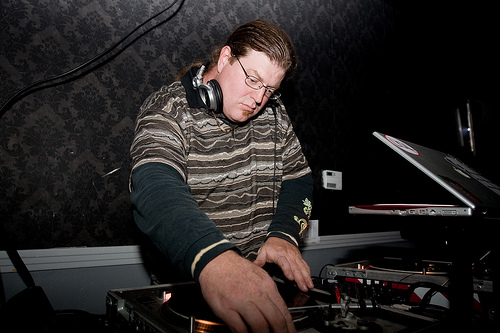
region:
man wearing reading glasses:
[231, 40, 288, 104]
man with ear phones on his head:
[173, 48, 239, 123]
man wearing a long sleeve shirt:
[130, 157, 240, 274]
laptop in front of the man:
[355, 118, 487, 243]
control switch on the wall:
[317, 156, 349, 193]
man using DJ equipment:
[186, 212, 308, 331]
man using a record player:
[108, 270, 345, 330]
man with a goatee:
[240, 108, 257, 120]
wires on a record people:
[317, 251, 373, 302]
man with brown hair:
[250, 28, 277, 53]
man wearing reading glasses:
[238, 69, 285, 99]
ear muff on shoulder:
[188, 75, 223, 118]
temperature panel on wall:
[312, 163, 351, 199]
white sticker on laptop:
[382, 130, 421, 162]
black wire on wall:
[51, 49, 97, 86]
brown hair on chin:
[237, 110, 255, 119]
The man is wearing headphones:
[193, 62, 221, 111]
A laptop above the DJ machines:
[348, 131, 496, 214]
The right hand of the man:
[201, 251, 295, 331]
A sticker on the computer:
[385, 135, 417, 155]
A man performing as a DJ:
[133, 20, 313, 331]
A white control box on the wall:
[323, 169, 343, 188]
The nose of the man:
[250, 83, 265, 103]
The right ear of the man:
[216, 45, 228, 72]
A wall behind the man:
[0, 2, 497, 252]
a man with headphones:
[140, 14, 306, 129]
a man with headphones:
[163, 18, 298, 130]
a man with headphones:
[137, 16, 317, 160]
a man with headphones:
[155, 23, 324, 155]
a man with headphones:
[155, 27, 347, 178]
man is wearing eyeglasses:
[211, 38, 298, 127]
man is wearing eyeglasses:
[215, 29, 272, 131]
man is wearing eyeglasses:
[217, 33, 298, 142]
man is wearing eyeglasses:
[185, 24, 309, 157]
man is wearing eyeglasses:
[198, 19, 313, 159]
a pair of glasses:
[229, 55, 279, 100]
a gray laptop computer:
[347, 128, 496, 218]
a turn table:
[111, 280, 425, 331]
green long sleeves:
[127, 160, 317, 277]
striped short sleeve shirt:
[130, 80, 315, 252]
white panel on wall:
[322, 167, 347, 190]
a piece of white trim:
[3, 231, 404, 331]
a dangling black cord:
[0, 3, 185, 249]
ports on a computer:
[394, 207, 437, 217]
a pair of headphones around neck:
[192, 60, 281, 120]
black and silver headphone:
[180, 59, 274, 113]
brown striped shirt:
[143, 75, 310, 255]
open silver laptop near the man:
[345, 119, 495, 217]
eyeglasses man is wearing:
[233, 60, 280, 105]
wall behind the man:
[4, 1, 499, 241]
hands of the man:
[206, 232, 315, 328]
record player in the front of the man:
[90, 258, 347, 332]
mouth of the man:
[239, 100, 256, 112]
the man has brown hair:
[129, 17, 316, 332]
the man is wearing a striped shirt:
[131, 18, 310, 330]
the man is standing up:
[127, 17, 318, 332]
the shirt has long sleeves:
[130, 79, 313, 279]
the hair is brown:
[177, 18, 297, 86]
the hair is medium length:
[174, 18, 295, 89]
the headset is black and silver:
[182, 60, 223, 113]